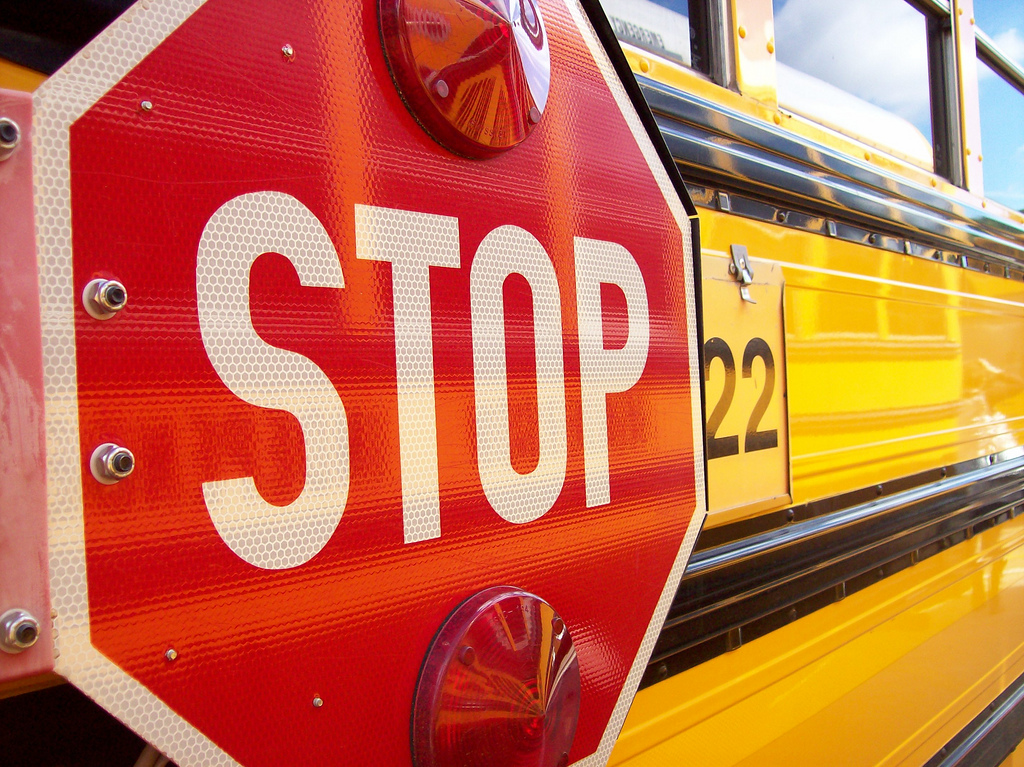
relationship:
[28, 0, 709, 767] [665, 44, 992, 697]
reflecting paint on a school bus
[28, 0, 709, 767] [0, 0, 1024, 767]
reflecting paint on side of bus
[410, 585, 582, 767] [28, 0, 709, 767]
light on reflecting paint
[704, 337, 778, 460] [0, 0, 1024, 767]
number on bus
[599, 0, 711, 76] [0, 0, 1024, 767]
bus window on bus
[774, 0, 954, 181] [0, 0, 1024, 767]
bus window on bus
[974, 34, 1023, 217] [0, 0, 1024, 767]
bus window on bus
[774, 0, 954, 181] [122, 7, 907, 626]
bus window on bus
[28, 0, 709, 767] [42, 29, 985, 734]
reflecting paint on bus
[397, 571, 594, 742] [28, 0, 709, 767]
light on reflecting paint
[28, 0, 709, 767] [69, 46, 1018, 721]
reflecting paint on bus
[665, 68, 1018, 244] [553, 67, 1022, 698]
paneling on bus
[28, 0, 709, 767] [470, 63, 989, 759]
reflecting paint on bus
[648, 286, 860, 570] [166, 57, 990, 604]
number on bus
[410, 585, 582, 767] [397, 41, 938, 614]
light on bus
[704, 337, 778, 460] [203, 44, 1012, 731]
number on bus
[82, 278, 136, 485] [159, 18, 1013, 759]
bolts on bus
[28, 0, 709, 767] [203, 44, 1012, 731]
reflecting paint on bus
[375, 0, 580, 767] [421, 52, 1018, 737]
lights on bus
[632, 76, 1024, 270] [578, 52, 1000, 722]
paneling on bus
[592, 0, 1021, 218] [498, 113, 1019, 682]
window on school bus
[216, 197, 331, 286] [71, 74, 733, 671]
pattern on sign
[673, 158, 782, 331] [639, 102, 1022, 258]
bolts on siding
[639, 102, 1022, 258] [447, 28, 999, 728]
siding on bus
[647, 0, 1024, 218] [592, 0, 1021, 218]
blue sky on window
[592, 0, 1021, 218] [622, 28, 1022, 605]
window on bus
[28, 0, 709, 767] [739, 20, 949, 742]
reflecting paint on a bus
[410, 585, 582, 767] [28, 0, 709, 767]
light on a reflecting paint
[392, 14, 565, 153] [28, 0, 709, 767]
light on a reflecting paint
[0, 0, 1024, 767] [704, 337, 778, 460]
bus has number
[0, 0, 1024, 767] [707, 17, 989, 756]
bus has side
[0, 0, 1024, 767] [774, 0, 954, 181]
bus has bus window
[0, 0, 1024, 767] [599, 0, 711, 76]
bus has bus window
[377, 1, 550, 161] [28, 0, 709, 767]
light on reflecting paint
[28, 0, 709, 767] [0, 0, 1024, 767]
reflecting paint of bus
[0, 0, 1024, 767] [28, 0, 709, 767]
bus has reflecting paint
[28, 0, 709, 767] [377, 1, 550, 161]
reflecting paint has light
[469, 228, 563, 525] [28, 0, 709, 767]
letter o on reflecting paint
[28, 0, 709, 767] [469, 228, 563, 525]
reflecting paint has letter o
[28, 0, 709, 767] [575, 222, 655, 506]
reflecting paint has letter p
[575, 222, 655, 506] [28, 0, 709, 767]
letter p on reflecting paint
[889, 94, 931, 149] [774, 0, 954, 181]
blue sky reflecting in bus window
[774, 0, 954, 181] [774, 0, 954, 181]
bus window reflecting in bus window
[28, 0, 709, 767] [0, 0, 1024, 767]
reflecting paint on bus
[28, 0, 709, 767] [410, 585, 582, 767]
reflecting paint has light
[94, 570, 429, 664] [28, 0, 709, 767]
reflecting paint on reflecting paint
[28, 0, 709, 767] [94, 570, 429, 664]
reflecting paint has reflecting paint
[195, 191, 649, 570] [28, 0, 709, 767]
lettering on reflecting paint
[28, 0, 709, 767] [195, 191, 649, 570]
reflecting paint has lettering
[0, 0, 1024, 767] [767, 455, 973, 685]
bus has paint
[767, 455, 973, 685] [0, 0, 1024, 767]
paint on bus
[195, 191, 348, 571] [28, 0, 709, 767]
letter on reflecting paint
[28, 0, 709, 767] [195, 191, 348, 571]
reflecting paint has letter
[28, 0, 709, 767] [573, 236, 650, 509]
reflecting paint has letter p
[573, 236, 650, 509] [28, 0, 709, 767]
letter p on reflecting paint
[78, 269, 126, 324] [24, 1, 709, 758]
bolt to sign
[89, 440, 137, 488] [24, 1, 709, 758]
bolt to sign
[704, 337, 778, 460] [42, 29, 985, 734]
number on bus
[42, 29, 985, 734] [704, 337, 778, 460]
bus has number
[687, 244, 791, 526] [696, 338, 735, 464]
background has black number